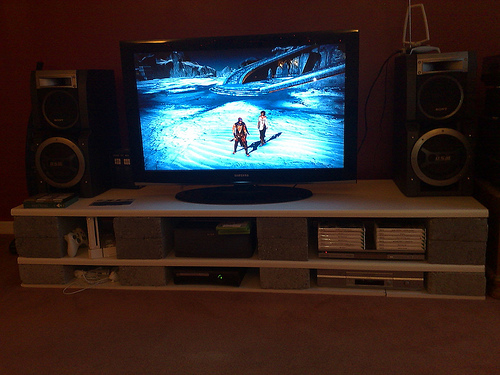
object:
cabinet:
[10, 178, 487, 302]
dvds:
[318, 227, 427, 251]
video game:
[308, 218, 430, 292]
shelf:
[308, 219, 425, 291]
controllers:
[73, 269, 119, 283]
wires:
[63, 270, 110, 295]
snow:
[147, 109, 224, 164]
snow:
[275, 109, 340, 165]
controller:
[64, 228, 89, 257]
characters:
[232, 111, 268, 157]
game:
[173, 267, 244, 287]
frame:
[24, 66, 111, 199]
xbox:
[171, 266, 244, 288]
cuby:
[310, 266, 430, 293]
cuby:
[159, 217, 258, 259]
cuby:
[164, 266, 263, 291]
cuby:
[53, 216, 118, 261]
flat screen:
[115, 33, 359, 183]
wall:
[5, 3, 495, 191]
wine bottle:
[376, 226, 428, 252]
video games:
[215, 222, 255, 236]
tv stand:
[174, 180, 312, 205]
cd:
[377, 227, 427, 251]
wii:
[87, 216, 103, 259]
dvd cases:
[24, 191, 79, 208]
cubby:
[304, 216, 432, 263]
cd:
[317, 227, 366, 251]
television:
[118, 28, 361, 205]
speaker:
[25, 63, 127, 199]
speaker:
[388, 41, 487, 197]